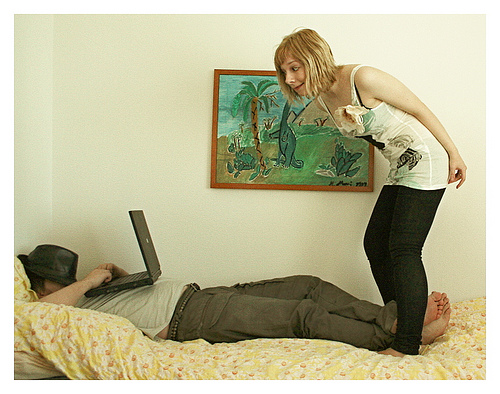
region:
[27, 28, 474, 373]
woman is standing on bed over man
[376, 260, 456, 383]
bare feet sticking out of pant legs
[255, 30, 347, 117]
woman has short blonde straight hair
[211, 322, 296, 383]
yellow sheets with orange and white flowers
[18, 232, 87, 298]
leather hat covering face of man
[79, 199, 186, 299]
black laptop resting on man's stomach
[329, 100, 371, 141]
flower made of fabric on shirt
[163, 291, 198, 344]
silver studs on black belt in belt loops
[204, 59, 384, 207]
painting hanging on the white wall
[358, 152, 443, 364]
skin tight black jeans on woman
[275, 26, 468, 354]
woman with blonde hair, black pants and a white shirt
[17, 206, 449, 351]
man with dark tan pants and a white shirt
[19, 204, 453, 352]
man with a black hat over his face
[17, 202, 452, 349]
man with a black laptop laying on his chest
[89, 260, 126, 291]
man's hands on the keyboard of a laptop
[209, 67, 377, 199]
brown framed art on a white wall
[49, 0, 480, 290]
white wall next to behind a bed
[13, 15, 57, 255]
white wall above man's head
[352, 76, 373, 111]
black strap under a white shirt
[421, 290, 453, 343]
bare feet of a man laying on a bed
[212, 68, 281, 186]
picture on the wall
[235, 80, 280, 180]
a palm tree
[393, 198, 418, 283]
the women is wearing black pants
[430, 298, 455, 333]
the mans feet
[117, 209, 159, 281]
a laptop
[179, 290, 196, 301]
man is wearing a belt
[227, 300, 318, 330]
the pants are brown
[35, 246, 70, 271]
black hat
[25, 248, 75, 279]
the hat is on mans face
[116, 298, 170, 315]
man is wearing a white shirt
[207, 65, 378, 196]
a large brown picture frame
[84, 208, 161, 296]
a black laptop computer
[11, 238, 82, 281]
a black hat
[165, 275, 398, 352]
a man's green pants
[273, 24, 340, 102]
a woman's short cut blonde hair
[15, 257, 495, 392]
part of a yellow flowered bedspread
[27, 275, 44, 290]
part of a man's dark hair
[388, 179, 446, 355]
the leg of a woman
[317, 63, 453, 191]
a woman's white tank top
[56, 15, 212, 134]
part of a painted white wall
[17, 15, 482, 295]
white walls of room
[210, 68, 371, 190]
framed painting on wall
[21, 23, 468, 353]
two people on bed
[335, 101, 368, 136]
flower on tank top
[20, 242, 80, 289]
black hat over face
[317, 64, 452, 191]
white tank top on woman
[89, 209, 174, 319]
open black laptop on stomach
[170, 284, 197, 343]
belt on gray pants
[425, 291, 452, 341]
toes on bare feet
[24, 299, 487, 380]
yellow print on bedspread